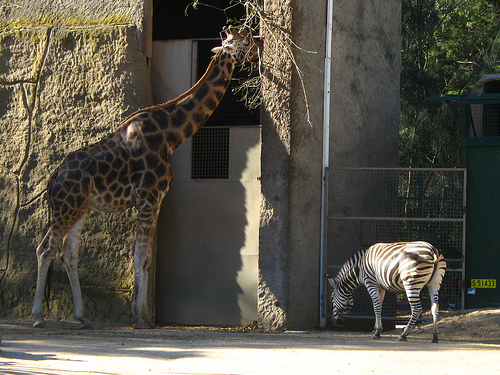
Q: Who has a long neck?
A: A giraffe.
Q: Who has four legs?
A: Both the giraffe and zebra.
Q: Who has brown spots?
A: Giraffe.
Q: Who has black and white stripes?
A: The zebra.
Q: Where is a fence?
A: In front of the zebra.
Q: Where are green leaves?
A: On a tree.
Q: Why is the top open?
A: So the giraffe can eat.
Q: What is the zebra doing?
A: Eating grass.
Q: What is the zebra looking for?
A: Food.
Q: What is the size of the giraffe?
A: Tall.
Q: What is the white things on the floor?
A: Back pair of giraffe's leg.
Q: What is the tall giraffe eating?
A: Grass.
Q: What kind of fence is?
A: Metal chain.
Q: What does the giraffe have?
A: Spots.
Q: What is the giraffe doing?
A: Eating.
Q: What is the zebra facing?
A: The wall.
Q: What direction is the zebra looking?
A: Down.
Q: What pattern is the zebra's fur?
A: Striped.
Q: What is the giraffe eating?
A: Leaves.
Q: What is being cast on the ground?
A: Shadows.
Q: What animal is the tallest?
A: Giraffe.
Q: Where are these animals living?
A: The zoo.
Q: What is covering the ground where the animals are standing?
A: Concrete.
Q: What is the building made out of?
A: Stone.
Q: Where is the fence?
A: Next to building.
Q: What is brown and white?
A: The giraffe.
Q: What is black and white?
A: The zebra.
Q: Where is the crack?
A: In the wall.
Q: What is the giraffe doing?
A: Standing tall.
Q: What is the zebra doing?
A: Bending over.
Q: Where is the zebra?
A: Next to the fence.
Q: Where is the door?
A: Next to the giraffe.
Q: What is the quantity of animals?
A: Two.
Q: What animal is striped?
A: The zebra.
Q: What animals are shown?
A: A giraffe and zebra.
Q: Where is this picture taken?
A: A zoo.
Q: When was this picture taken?
A: Daytime.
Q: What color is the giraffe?
A: Brown and white.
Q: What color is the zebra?
A: Black and white.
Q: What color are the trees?
A: Green.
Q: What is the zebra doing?
A: Grazing.